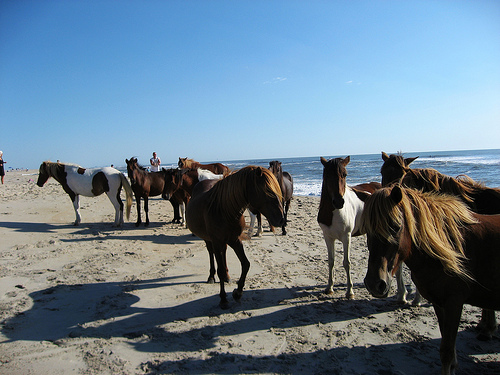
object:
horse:
[185, 166, 287, 312]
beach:
[0, 169, 500, 375]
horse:
[35, 162, 133, 227]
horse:
[125, 156, 181, 228]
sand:
[0, 168, 500, 375]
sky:
[0, 0, 500, 168]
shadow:
[2, 271, 194, 339]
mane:
[410, 187, 480, 282]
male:
[150, 152, 161, 173]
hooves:
[218, 298, 229, 309]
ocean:
[89, 151, 498, 196]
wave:
[421, 152, 498, 164]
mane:
[261, 168, 282, 201]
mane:
[137, 163, 147, 170]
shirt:
[150, 157, 159, 172]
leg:
[231, 240, 251, 301]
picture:
[0, 0, 497, 375]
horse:
[352, 190, 500, 375]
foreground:
[1, 197, 500, 375]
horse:
[317, 156, 381, 299]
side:
[466, 6, 500, 374]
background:
[1, 0, 500, 165]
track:
[146, 240, 199, 284]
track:
[297, 194, 320, 282]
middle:
[211, 0, 296, 372]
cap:
[414, 154, 497, 164]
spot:
[91, 171, 110, 196]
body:
[50, 163, 122, 197]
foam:
[290, 177, 323, 197]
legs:
[323, 228, 336, 295]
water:
[210, 148, 500, 187]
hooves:
[344, 291, 354, 300]